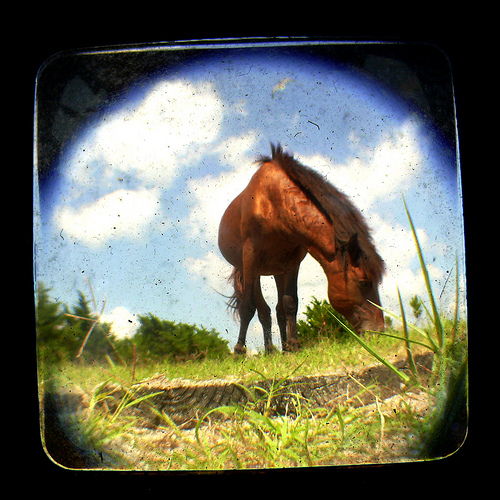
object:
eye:
[356, 277, 373, 294]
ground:
[38, 320, 466, 470]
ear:
[345, 229, 364, 267]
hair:
[224, 209, 243, 231]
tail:
[213, 263, 246, 324]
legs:
[236, 239, 258, 343]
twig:
[76, 296, 110, 358]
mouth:
[353, 331, 378, 339]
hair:
[303, 183, 338, 194]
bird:
[265, 71, 295, 96]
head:
[326, 232, 386, 338]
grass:
[324, 191, 459, 395]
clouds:
[94, 80, 224, 180]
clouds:
[213, 132, 255, 163]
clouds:
[53, 185, 166, 250]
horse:
[207, 141, 385, 353]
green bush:
[126, 309, 230, 362]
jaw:
[326, 288, 351, 320]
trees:
[292, 294, 342, 339]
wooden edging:
[99, 350, 434, 429]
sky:
[34, 58, 465, 352]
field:
[37, 319, 472, 470]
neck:
[268, 159, 373, 273]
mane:
[250, 140, 388, 285]